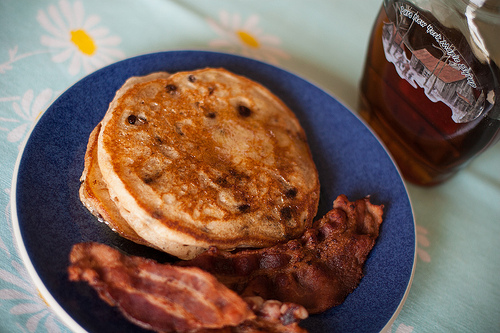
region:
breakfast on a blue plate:
[11, 47, 419, 331]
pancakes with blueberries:
[81, 68, 318, 250]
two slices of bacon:
[63, 187, 390, 331]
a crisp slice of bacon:
[197, 188, 384, 313]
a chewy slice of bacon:
[61, 242, 308, 332]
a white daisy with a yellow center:
[29, 8, 126, 76]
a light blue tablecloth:
[0, 10, 363, 71]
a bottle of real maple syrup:
[354, 0, 499, 190]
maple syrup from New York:
[356, 0, 498, 186]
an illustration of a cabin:
[372, 23, 483, 125]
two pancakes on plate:
[84, 60, 319, 240]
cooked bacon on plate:
[121, 198, 394, 331]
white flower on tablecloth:
[37, 5, 127, 68]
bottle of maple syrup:
[352, 14, 492, 168]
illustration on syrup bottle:
[383, 21, 483, 112]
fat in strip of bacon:
[210, 279, 239, 305]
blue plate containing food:
[308, 79, 355, 183]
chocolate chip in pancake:
[235, 96, 256, 123]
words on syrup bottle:
[408, 10, 462, 58]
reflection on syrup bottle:
[460, 11, 488, 48]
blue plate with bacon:
[10, 33, 425, 324]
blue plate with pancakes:
[8, 43, 421, 324]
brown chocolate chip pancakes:
[80, 55, 320, 258]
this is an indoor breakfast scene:
[3, 0, 494, 326]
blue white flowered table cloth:
[5, 0, 495, 321]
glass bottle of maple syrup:
[360, 0, 496, 190]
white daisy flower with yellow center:
[37, 0, 132, 80]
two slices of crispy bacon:
[76, 187, 387, 325]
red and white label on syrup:
[371, 2, 498, 124]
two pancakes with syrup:
[78, 54, 330, 261]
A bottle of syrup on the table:
[356, 0, 498, 190]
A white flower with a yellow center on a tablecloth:
[33, 0, 130, 72]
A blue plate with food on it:
[10, 46, 417, 331]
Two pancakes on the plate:
[77, 66, 314, 249]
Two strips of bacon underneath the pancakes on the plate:
[66, 203, 395, 330]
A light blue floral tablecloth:
[0, 0, 374, 57]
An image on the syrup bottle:
[383, 8, 493, 134]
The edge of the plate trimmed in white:
[0, 158, 56, 331]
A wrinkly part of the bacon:
[286, 195, 386, 252]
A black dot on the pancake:
[231, 94, 260, 124]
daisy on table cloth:
[33, 3, 123, 89]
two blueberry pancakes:
[78, 60, 328, 246]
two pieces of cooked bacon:
[67, 219, 415, 331]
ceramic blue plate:
[16, 89, 108, 254]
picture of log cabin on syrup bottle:
[392, 50, 479, 102]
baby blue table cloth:
[429, 184, 490, 320]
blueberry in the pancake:
[122, 106, 148, 136]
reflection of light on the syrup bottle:
[447, 0, 496, 72]